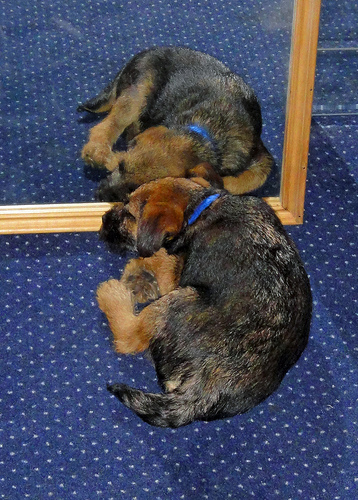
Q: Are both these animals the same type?
A: Yes, all the animals are dogs.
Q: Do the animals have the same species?
A: Yes, all the animals are dogs.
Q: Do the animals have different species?
A: No, all the animals are dogs.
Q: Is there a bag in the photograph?
A: No, there are no bags.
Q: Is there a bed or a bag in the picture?
A: No, there are no bags or beds.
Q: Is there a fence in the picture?
A: No, there are no fences.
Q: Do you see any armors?
A: No, there are no armors.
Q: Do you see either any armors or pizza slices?
A: No, there are no armors or pizza slices.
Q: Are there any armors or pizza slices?
A: No, there are no armors or pizza slices.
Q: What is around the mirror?
A: The frame is around the mirror.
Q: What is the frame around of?
A: The frame is around the mirror.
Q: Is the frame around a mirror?
A: Yes, the frame is around a mirror.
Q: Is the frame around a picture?
A: No, the frame is around a mirror.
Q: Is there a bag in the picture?
A: No, there are no bags.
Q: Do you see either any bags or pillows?
A: No, there are no bags or pillows.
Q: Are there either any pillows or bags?
A: No, there are no bags or pillows.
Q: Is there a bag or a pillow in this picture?
A: No, there are no bags or pillows.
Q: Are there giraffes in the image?
A: No, there are no giraffes.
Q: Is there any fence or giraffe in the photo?
A: No, there are no giraffes or fences.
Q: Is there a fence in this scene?
A: No, there are no fences.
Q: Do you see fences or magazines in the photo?
A: No, there are no fences or magazines.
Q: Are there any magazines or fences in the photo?
A: No, there are no fences or magazines.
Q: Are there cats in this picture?
A: No, there are no cats.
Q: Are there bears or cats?
A: No, there are no cats or bears.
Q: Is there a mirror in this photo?
A: Yes, there is a mirror.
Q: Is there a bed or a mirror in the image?
A: Yes, there is a mirror.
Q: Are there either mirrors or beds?
A: Yes, there is a mirror.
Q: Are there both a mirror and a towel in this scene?
A: No, there is a mirror but no towels.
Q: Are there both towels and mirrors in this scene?
A: No, there is a mirror but no towels.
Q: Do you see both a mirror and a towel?
A: No, there is a mirror but no towels.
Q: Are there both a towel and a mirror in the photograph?
A: No, there is a mirror but no towels.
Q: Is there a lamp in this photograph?
A: No, there are no lamps.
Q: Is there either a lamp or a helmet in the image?
A: No, there are no lamps or helmets.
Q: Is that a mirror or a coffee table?
A: That is a mirror.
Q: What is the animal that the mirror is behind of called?
A: The animal is a dog.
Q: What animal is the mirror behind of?
A: The mirror is behind the dog.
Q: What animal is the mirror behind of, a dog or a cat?
A: The mirror is behind a dog.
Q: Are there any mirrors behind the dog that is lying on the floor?
A: Yes, there is a mirror behind the dog.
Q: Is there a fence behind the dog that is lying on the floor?
A: No, there is a mirror behind the dog.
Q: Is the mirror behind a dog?
A: Yes, the mirror is behind a dog.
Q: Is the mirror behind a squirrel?
A: No, the mirror is behind a dog.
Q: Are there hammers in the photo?
A: No, there are no hammers.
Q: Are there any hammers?
A: No, there are no hammers.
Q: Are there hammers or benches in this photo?
A: No, there are no hammers or benches.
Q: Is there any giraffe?
A: No, there are no giraffes.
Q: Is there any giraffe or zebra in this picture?
A: No, there are no giraffes or zebras.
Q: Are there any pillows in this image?
A: No, there are no pillows.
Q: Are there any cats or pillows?
A: No, there are no pillows or cats.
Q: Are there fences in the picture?
A: No, there are no fences.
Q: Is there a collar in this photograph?
A: Yes, there is a collar.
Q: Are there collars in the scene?
A: Yes, there is a collar.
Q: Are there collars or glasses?
A: Yes, there is a collar.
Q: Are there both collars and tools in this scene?
A: No, there is a collar but no tools.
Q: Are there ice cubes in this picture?
A: No, there are no ice cubes.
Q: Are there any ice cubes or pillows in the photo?
A: No, there are no ice cubes or pillows.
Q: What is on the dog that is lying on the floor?
A: The collar is on the dog.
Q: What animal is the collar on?
A: The collar is on the dog.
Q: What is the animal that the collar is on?
A: The animal is a dog.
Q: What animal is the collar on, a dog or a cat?
A: The collar is on a dog.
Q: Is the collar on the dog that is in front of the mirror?
A: Yes, the collar is on the dog.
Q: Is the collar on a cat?
A: No, the collar is on the dog.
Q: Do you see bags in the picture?
A: No, there are no bags.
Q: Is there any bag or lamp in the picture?
A: No, there are no bags or lamps.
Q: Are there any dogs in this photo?
A: Yes, there is a dog.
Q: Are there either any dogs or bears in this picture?
A: Yes, there is a dog.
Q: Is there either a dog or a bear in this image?
A: Yes, there is a dog.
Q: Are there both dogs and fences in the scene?
A: No, there is a dog but no fences.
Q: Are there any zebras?
A: No, there are no zebras.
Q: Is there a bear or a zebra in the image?
A: No, there are no zebras or bears.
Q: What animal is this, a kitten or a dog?
A: This is a dog.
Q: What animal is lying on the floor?
A: The dog is lying on the floor.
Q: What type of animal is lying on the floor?
A: The animal is a dog.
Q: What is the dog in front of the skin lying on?
A: The dog is lying on the floor.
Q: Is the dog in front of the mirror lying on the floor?
A: Yes, the dog is lying on the floor.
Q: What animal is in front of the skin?
A: The dog is in front of the skin.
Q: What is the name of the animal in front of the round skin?
A: The animal is a dog.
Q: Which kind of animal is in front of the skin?
A: The animal is a dog.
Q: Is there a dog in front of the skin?
A: Yes, there is a dog in front of the skin.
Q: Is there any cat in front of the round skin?
A: No, there is a dog in front of the skin.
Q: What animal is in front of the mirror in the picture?
A: The dog is in front of the mirror.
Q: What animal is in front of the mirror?
A: The dog is in front of the mirror.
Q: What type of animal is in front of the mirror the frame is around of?
A: The animal is a dog.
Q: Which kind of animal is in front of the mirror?
A: The animal is a dog.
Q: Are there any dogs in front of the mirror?
A: Yes, there is a dog in front of the mirror.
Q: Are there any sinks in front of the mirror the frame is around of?
A: No, there is a dog in front of the mirror.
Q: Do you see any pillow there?
A: No, there are no pillows.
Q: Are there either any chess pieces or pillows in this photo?
A: No, there are no pillows or chess pieces.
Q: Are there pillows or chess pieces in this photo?
A: No, there are no pillows or chess pieces.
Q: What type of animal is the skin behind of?
A: The skin is behind the dog.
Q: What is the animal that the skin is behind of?
A: The animal is a dog.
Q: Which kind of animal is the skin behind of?
A: The skin is behind the dog.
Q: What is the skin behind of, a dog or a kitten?
A: The skin is behind a dog.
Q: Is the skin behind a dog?
A: Yes, the skin is behind a dog.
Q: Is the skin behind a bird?
A: No, the skin is behind a dog.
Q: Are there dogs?
A: Yes, there is a dog.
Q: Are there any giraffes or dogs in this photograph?
A: Yes, there is a dog.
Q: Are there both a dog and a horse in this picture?
A: No, there is a dog but no horses.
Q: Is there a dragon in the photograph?
A: No, there are no dragons.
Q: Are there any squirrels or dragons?
A: No, there are no dragons or squirrels.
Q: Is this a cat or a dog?
A: This is a dog.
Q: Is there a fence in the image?
A: No, there are no fences.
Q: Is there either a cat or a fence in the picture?
A: No, there are no fences or cats.